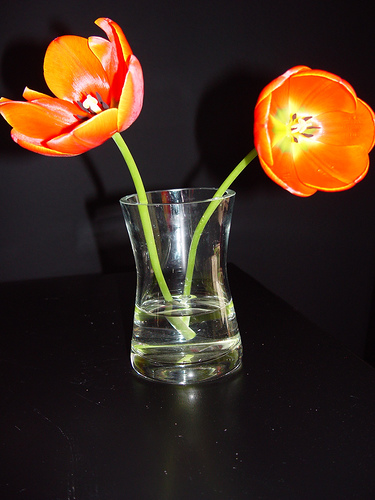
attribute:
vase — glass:
[119, 185, 245, 385]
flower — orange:
[252, 63, 373, 194]